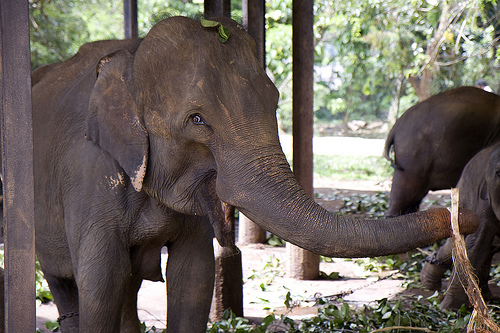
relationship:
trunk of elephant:
[217, 147, 482, 258] [31, 14, 477, 331]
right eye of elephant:
[188, 112, 210, 126] [31, 14, 477, 331]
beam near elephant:
[293, 0, 317, 279] [31, 14, 477, 331]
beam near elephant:
[238, 0, 267, 242] [31, 14, 477, 331]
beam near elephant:
[203, 0, 243, 325] [31, 14, 477, 331]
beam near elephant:
[122, 0, 138, 41] [31, 14, 477, 331]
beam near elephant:
[2, 1, 35, 332] [31, 14, 477, 331]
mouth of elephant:
[201, 169, 248, 250] [31, 14, 477, 331]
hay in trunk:
[449, 189, 499, 332] [217, 147, 482, 258]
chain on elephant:
[56, 309, 82, 325] [31, 14, 477, 331]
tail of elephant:
[381, 130, 404, 174] [381, 86, 499, 218]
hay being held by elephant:
[449, 189, 499, 332] [31, 14, 477, 331]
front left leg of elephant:
[165, 223, 215, 331] [31, 14, 477, 331]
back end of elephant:
[367, 92, 448, 220] [381, 86, 499, 218]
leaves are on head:
[197, 15, 233, 43] [132, 11, 284, 215]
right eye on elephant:
[188, 112, 210, 126] [31, 14, 477, 331]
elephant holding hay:
[31, 14, 477, 331] [449, 189, 499, 332]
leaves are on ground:
[195, 293, 499, 332] [0, 137, 499, 332]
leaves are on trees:
[32, 0, 499, 129] [31, 2, 500, 134]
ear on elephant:
[82, 47, 151, 194] [31, 14, 477, 331]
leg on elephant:
[62, 214, 136, 332] [31, 14, 477, 331]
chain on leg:
[339, 252, 451, 299] [417, 236, 458, 292]